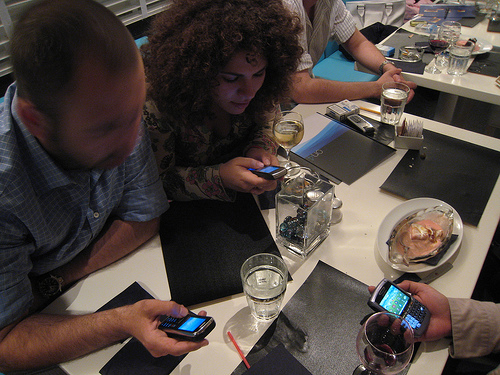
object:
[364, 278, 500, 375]
person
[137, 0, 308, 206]
girl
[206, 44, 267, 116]
face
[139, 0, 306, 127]
head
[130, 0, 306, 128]
hair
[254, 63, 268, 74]
eyebrow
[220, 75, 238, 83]
eye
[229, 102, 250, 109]
lips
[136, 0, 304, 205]
woman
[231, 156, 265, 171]
thumbs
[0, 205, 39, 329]
sleeve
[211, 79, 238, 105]
cheek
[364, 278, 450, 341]
palm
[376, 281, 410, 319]
screen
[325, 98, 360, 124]
packets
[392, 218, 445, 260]
food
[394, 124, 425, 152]
box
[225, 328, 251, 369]
straw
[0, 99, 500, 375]
table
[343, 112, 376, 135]
cellphone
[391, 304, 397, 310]
apps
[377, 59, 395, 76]
watch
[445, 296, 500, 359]
arm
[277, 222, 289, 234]
marbles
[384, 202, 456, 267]
fish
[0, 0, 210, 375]
man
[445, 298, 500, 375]
shirt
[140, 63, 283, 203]
jacket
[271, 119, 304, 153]
wine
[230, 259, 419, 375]
mat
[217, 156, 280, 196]
hand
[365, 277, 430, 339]
phone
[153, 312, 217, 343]
cell phone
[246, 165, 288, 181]
cell phone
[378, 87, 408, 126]
water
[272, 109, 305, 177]
wine glass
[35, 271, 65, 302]
watch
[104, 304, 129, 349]
wrist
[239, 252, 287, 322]
glass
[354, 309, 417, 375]
glass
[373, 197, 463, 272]
plate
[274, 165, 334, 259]
container